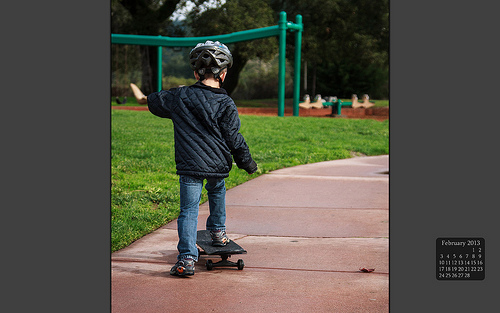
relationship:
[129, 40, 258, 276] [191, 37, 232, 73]
boy wearing helmet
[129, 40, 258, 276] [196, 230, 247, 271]
boy on board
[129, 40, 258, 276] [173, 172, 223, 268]
boy wearing jeans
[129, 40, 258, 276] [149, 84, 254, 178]
boy wearing coat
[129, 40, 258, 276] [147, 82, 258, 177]
boy wearing coat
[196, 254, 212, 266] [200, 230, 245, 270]
wheel on board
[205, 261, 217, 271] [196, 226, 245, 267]
wheel on board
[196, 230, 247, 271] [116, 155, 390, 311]
board on sidewalk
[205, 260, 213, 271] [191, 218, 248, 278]
wheel on skateboard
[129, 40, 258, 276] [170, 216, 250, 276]
boy riding a skateboard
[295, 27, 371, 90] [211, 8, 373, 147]
trees behind playground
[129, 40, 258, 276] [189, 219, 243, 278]
boy on skateboard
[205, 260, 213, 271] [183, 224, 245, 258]
wheel of skateboard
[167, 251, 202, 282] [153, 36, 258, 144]
shoe of child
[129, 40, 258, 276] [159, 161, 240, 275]
boy wearing jeans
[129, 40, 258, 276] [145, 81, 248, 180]
boy has a jacket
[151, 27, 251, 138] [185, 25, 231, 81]
boy has on helmet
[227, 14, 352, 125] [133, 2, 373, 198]
playground in park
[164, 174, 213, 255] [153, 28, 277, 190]
leg of a boy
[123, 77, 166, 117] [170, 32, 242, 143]
hand of a boy